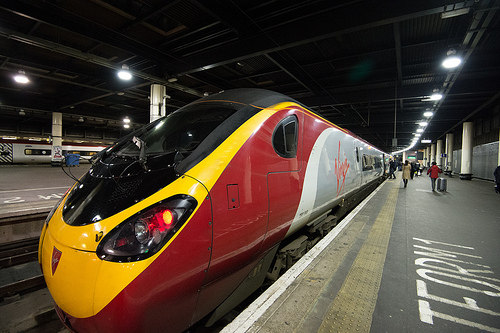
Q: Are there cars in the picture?
A: No, there are no cars.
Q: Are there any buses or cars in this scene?
A: No, there are no cars or buses.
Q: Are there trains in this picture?
A: Yes, there is a train.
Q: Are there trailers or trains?
A: Yes, there is a train.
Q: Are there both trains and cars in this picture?
A: No, there is a train but no cars.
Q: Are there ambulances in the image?
A: No, there are no ambulances.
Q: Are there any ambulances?
A: No, there are no ambulances.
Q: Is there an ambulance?
A: No, there are no ambulances.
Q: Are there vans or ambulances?
A: No, there are no ambulances or vans.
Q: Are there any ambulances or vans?
A: No, there are no ambulances or vans.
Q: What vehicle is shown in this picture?
A: The vehicle is a train.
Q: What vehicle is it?
A: The vehicle is a train.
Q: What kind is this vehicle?
A: This is a train.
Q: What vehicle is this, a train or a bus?
A: This is a train.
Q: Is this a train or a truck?
A: This is a train.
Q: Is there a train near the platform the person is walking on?
A: Yes, there is a train near the platform.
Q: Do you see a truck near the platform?
A: No, there is a train near the platform.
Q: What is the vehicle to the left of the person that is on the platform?
A: The vehicle is a train.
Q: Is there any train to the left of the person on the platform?
A: Yes, there is a train to the left of the person.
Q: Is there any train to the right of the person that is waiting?
A: No, the train is to the left of the person.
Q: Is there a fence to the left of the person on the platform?
A: No, there is a train to the left of the person.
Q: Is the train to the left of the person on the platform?
A: Yes, the train is to the left of the person.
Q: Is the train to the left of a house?
A: No, the train is to the left of the person.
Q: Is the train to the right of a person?
A: No, the train is to the left of a person.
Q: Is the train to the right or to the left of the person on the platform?
A: The train is to the left of the person.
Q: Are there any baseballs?
A: No, there are no baseballs.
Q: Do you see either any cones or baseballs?
A: No, there are no baseballs or cones.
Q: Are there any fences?
A: No, there are no fences.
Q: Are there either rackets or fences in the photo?
A: No, there are no fences or rackets.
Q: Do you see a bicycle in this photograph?
A: No, there are no bicycles.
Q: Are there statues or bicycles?
A: No, there are no bicycles or statues.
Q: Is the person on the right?
A: Yes, the person is on the right of the image.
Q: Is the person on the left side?
A: No, the person is on the right of the image.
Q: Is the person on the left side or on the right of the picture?
A: The person is on the right of the image.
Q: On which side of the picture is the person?
A: The person is on the right of the image.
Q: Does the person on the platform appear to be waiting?
A: Yes, the person is waiting.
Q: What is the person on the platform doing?
A: The person is waiting.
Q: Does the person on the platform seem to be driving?
A: No, the person is waiting.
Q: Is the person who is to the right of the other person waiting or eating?
A: The person is waiting.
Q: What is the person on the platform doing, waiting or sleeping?
A: The person is waiting.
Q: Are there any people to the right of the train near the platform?
A: Yes, there is a person to the right of the train.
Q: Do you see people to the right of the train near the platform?
A: Yes, there is a person to the right of the train.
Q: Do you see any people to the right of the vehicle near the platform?
A: Yes, there is a person to the right of the train.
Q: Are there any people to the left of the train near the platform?
A: No, the person is to the right of the train.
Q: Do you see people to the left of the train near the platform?
A: No, the person is to the right of the train.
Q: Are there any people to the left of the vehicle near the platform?
A: No, the person is to the right of the train.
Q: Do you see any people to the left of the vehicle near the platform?
A: No, the person is to the right of the train.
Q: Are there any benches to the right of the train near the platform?
A: No, there is a person to the right of the train.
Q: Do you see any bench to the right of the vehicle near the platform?
A: No, there is a person to the right of the train.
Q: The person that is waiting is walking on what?
A: The person is walking on the platform.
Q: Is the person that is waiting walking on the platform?
A: Yes, the person is walking on the platform.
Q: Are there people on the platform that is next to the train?
A: Yes, there is a person on the platform.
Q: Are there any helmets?
A: No, there are no helmets.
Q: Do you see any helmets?
A: No, there are no helmets.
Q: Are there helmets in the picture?
A: No, there are no helmets.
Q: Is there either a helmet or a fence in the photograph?
A: No, there are no helmets or fences.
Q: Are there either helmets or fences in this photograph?
A: No, there are no helmets or fences.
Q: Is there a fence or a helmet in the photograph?
A: No, there are no helmets or fences.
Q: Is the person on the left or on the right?
A: The person is on the right of the image.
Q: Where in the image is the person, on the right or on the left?
A: The person is on the right of the image.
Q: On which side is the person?
A: The person is on the right of the image.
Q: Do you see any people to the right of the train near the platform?
A: Yes, there is a person to the right of the train.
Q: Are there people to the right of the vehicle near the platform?
A: Yes, there is a person to the right of the train.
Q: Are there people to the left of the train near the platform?
A: No, the person is to the right of the train.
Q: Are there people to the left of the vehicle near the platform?
A: No, the person is to the right of the train.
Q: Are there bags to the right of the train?
A: No, there is a person to the right of the train.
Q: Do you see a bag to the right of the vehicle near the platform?
A: No, there is a person to the right of the train.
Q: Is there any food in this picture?
A: No, there is no food.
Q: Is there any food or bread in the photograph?
A: No, there are no food or breads.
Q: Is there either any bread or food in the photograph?
A: No, there are no food or breads.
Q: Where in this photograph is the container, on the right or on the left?
A: The container is on the left of the image.